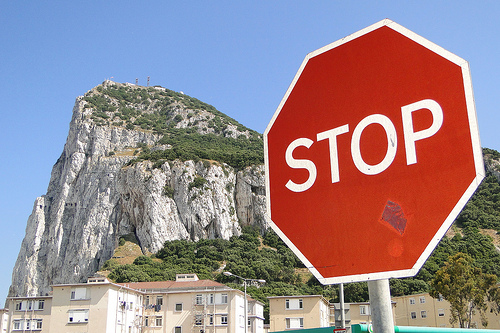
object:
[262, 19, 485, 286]
sign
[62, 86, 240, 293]
formation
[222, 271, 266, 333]
street lamp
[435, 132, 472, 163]
ground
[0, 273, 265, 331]
building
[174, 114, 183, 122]
trees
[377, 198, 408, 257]
smudge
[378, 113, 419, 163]
ground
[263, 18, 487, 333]
post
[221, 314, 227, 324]
window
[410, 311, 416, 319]
windows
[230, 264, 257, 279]
plants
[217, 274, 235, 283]
plants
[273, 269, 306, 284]
plants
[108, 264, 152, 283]
plants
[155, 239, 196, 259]
plants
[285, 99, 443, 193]
white writing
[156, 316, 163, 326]
windows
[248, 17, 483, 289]
wood fence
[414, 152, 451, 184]
ground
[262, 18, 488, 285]
stop sign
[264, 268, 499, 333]
building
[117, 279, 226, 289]
roof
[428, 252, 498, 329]
tree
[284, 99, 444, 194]
"stop"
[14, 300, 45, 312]
balconies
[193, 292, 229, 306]
balconies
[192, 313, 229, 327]
balconies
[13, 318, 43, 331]
balconies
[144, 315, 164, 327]
balconies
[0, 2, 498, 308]
sky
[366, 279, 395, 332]
pole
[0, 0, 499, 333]
background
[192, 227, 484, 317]
wall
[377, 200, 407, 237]
paint